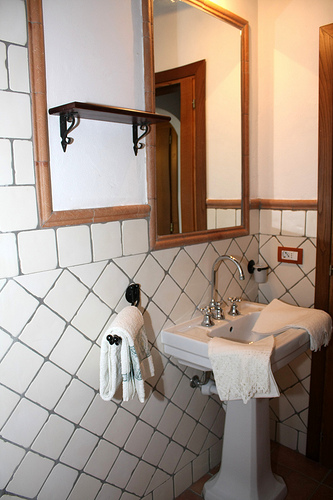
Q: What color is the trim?
A: Brown.